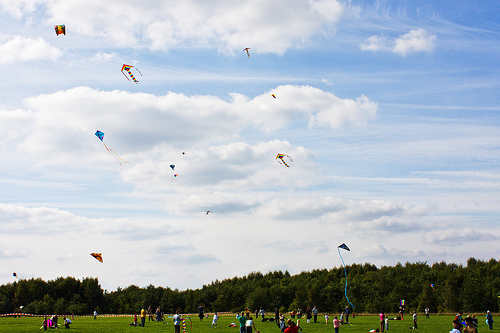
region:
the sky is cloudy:
[35, 14, 483, 99]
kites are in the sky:
[79, 235, 156, 285]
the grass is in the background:
[227, 253, 266, 299]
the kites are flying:
[310, 233, 370, 320]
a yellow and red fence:
[14, 306, 126, 331]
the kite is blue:
[329, 235, 361, 294]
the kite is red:
[84, 243, 154, 282]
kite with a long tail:
[111, 56, 145, 91]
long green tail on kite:
[335, 246, 357, 312]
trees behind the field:
[239, 265, 469, 307]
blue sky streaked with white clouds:
[300, 13, 463, 204]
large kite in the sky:
[44, 19, 65, 44]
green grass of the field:
[78, 316, 116, 331]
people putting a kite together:
[36, 313, 71, 332]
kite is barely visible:
[196, 193, 216, 223]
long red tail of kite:
[102, 133, 132, 173]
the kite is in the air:
[53, 23, 65, 35]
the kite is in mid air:
[117, 60, 142, 83]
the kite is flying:
[242, 45, 250, 60]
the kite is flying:
[274, 150, 293, 167]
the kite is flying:
[118, 59, 140, 84]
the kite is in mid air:
[89, 250, 104, 262]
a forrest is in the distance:
[6, 252, 496, 312]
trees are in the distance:
[2, 255, 497, 317]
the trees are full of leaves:
[2, 260, 498, 307]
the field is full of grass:
[2, 305, 497, 331]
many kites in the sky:
[6, 17, 366, 281]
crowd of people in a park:
[19, 297, 497, 329]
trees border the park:
[7, 260, 499, 316]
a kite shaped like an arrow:
[121, 58, 144, 86]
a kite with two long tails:
[274, 146, 292, 171]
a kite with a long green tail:
[334, 238, 349, 304]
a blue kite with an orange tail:
[90, 122, 117, 160]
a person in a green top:
[237, 312, 248, 329]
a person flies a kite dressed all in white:
[212, 308, 220, 332]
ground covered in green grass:
[0, 308, 498, 332]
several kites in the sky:
[43, 17, 363, 272]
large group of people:
[6, 303, 499, 332]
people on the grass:
[0, 301, 494, 331]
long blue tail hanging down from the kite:
[334, 248, 361, 311]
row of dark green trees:
[0, 255, 499, 315]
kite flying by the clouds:
[271, 150, 291, 171]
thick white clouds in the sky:
[3, 0, 499, 293]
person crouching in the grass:
[61, 316, 76, 328]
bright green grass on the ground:
[2, 308, 499, 331]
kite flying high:
[51, 20, 71, 40]